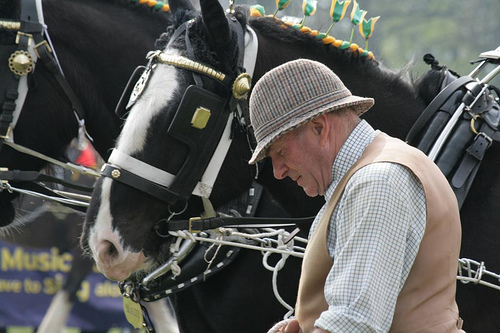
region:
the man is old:
[249, 72, 482, 329]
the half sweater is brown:
[293, 147, 470, 327]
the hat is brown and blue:
[244, 72, 382, 144]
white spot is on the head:
[100, 90, 207, 160]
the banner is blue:
[3, 243, 120, 330]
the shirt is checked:
[339, 220, 381, 330]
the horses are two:
[11, 3, 493, 308]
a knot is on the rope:
[240, 240, 298, 291]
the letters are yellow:
[7, 255, 42, 294]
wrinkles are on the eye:
[282, 130, 295, 150]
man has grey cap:
[222, 54, 404, 175]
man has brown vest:
[270, 168, 445, 326]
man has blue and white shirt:
[321, 145, 463, 319]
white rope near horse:
[177, 198, 338, 305]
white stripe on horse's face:
[44, 48, 209, 243]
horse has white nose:
[67, 227, 165, 331]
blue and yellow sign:
[2, 237, 72, 304]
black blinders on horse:
[118, 75, 230, 170]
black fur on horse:
[270, 21, 422, 145]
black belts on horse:
[405, 57, 497, 217]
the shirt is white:
[343, 180, 416, 331]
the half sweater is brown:
[294, 171, 461, 331]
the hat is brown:
[245, 78, 377, 145]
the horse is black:
[99, 0, 496, 325]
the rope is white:
[237, 226, 305, 281]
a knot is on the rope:
[260, 225, 292, 280]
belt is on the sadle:
[418, 75, 496, 167]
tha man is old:
[243, 42, 478, 329]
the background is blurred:
[392, 5, 493, 63]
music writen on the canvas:
[3, 244, 108, 309]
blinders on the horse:
[121, 60, 239, 148]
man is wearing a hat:
[224, 67, 374, 152]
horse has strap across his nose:
[103, 138, 193, 203]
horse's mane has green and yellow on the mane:
[276, 0, 386, 53]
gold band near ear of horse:
[141, 22, 261, 101]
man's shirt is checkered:
[349, 188, 448, 330]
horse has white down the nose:
[96, 15, 196, 300]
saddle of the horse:
[413, 52, 496, 186]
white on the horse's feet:
[13, 265, 180, 329]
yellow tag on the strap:
[120, 283, 169, 331]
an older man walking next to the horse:
[228, 42, 483, 277]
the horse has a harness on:
[68, 2, 269, 332]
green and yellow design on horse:
[267, 0, 385, 63]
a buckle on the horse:
[4, 40, 39, 85]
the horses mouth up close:
[71, 155, 228, 307]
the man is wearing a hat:
[221, 34, 436, 215]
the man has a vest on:
[226, 36, 491, 329]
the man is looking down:
[207, 39, 414, 210]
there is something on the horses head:
[107, 15, 252, 103]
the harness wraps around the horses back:
[391, 20, 498, 224]